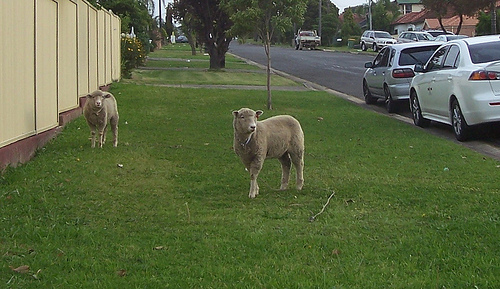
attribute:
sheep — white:
[82, 87, 313, 199]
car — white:
[407, 31, 497, 143]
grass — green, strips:
[2, 42, 500, 287]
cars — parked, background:
[295, 25, 499, 141]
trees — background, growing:
[173, 0, 308, 108]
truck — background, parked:
[297, 25, 321, 52]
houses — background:
[340, 1, 499, 47]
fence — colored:
[1, 1, 122, 175]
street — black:
[229, 39, 499, 156]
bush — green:
[121, 34, 151, 81]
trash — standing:
[345, 36, 357, 50]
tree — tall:
[224, 1, 311, 111]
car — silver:
[361, 41, 442, 111]